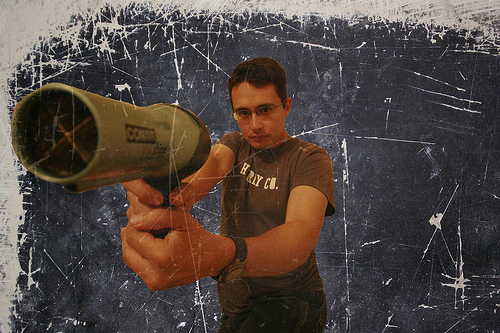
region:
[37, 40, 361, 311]
man holding a hair dryer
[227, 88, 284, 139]
man wearing eyeglasses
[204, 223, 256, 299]
black watch on man's wrist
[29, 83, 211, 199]
green conair hair dryer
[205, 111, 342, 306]
brown t-shirt with white lettering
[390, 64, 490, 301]
white scratch and paint marks on wall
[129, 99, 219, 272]
black handle of hair dryer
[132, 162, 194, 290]
two hands holding hair dryer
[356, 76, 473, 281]
black wall with white marks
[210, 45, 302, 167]
man with brown hair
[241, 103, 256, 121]
the man's left eye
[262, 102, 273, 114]
the man's right eye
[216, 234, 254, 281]
the man's watch on his wrist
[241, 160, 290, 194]
the white letters on the man's shirt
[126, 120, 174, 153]
conair brand hair dryer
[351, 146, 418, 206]
the blue background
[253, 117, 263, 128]
the man's nose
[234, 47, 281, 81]
the man's black hair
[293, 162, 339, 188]
the man's brown shirt sleeve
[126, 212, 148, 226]
the man's finger nails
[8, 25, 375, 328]
A man holding a blow dryer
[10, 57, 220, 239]
A blowdryer pointed straight ahead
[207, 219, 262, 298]
A watch on a man's arm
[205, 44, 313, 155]
A man wearing glasses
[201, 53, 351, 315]
A man wearing a t-shirt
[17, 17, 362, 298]
A man pointing a blow dryer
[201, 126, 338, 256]
Short sleeve shirt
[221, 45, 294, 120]
Brown hair parted in the middle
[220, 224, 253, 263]
The band of a watch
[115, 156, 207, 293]
Hands holding a blow dryer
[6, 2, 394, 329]
a man with a blow dryer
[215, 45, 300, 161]
a man's serious looking face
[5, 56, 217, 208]
a brown blow dryer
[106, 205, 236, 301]
a man's hand holding something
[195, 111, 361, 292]
a man's t-shirt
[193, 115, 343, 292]
a brown t-shirt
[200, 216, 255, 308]
a man's watch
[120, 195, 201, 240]
a man's thumb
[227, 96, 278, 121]
a man's eyeglasses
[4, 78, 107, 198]
the nozzle of a blow dryer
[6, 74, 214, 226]
A blow dryer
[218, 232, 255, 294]
A black wrist watch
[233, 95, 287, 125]
A young man wearing a brown t-shirt.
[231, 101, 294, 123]
A pair of eyeglasses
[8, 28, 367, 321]
A young man pointing a hair blow dryer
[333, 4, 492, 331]
A background of a scratched up wall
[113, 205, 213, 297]
A left hand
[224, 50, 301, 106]
Dark brown hair on top of head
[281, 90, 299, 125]
Left human ear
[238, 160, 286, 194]
A logo on front of brown t-shirt